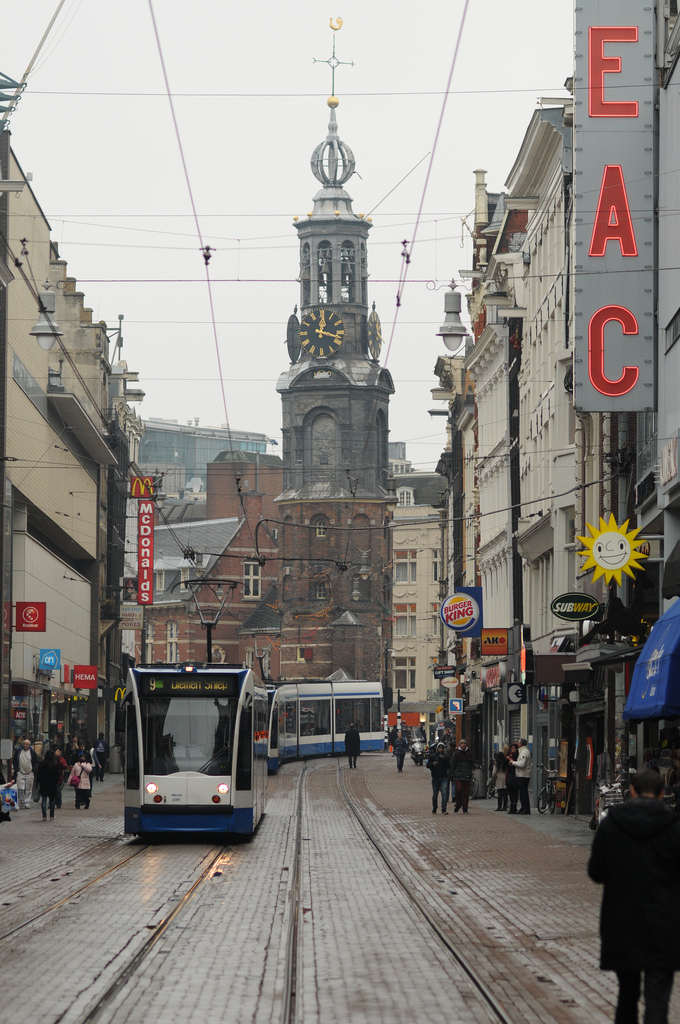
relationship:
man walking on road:
[448, 738, 477, 815] [257, 807, 569, 1024]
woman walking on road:
[424, 741, 452, 816] [257, 807, 569, 1024]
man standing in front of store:
[512, 740, 536, 811] [540, 702, 605, 804]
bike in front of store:
[537, 765, 565, 816] [537, 696, 613, 773]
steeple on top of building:
[287, 19, 377, 218] [265, 215, 389, 589]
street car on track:
[124, 660, 387, 844] [98, 841, 235, 916]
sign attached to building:
[126, 474, 164, 611] [32, 435, 129, 697]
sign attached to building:
[540, 577, 605, 631] [563, 427, 659, 765]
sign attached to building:
[439, 587, 489, 642] [446, 302, 582, 659]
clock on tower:
[296, 310, 355, 360] [271, 201, 395, 388]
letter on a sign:
[587, 24, 645, 117] [570, 17, 659, 417]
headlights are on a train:
[137, 778, 238, 802] [115, 651, 352, 831]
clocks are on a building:
[293, 304, 351, 362] [199, 186, 441, 678]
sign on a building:
[549, 589, 603, 621] [472, 316, 635, 747]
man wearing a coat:
[595, 770, 659, 1003] [616, 809, 659, 846]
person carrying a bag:
[31, 748, 62, 824] [68, 770, 81, 787]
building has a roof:
[163, 501, 318, 651] [179, 521, 227, 555]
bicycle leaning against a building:
[530, 759, 573, 813] [483, 501, 609, 724]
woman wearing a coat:
[68, 754, 102, 804] [75, 760, 91, 790]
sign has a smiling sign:
[575, 516, 647, 590] [575, 511, 650, 589]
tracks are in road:
[226, 797, 433, 961] [391, 807, 569, 978]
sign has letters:
[546, 589, 607, 622] [551, 599, 604, 613]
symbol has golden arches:
[131, 473, 154, 497] [130, 478, 147, 497]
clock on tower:
[300, 311, 350, 360] [279, 161, 389, 410]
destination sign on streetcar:
[157, 673, 246, 697] [115, 655, 391, 840]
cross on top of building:
[303, 20, 357, 94] [263, 15, 406, 746]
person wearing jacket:
[416, 737, 465, 813] [416, 747, 458, 776]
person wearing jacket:
[454, 737, 488, 818] [446, 749, 478, 798]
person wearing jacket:
[503, 734, 545, 813] [505, 749, 532, 778]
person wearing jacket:
[580, 762, 678, 1021] [580, 809, 676, 959]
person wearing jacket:
[28, 737, 72, 821] [28, 757, 65, 801]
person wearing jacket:
[63, 752, 97, 803] [70, 762, 102, 791]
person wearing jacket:
[384, 720, 416, 776] [384, 732, 408, 754]